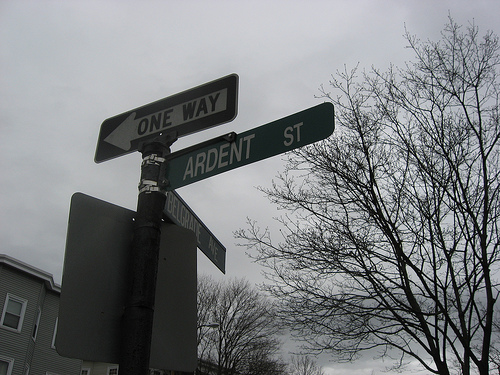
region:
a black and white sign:
[93, 73, 240, 165]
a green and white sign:
[166, 100, 337, 192]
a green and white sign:
[163, 186, 225, 271]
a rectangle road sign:
[54, 193, 198, 373]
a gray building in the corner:
[1, 253, 121, 374]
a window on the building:
[3, 293, 25, 330]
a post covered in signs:
[55, 73, 337, 374]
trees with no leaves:
[189, 13, 496, 370]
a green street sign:
[170, 101, 336, 188]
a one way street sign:
[93, 71, 238, 162]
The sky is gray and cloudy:
[16, 6, 388, 63]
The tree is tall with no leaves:
[303, 15, 499, 370]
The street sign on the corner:
[43, 60, 340, 372]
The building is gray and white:
[4, 244, 119, 373]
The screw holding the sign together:
[218, 121, 239, 144]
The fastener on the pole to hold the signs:
[135, 149, 172, 203]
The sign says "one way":
[80, 68, 255, 165]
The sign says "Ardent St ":
[168, 99, 336, 195]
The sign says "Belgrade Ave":
[159, 183, 231, 276]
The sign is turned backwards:
[58, 180, 210, 372]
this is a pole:
[108, 144, 173, 353]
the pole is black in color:
[106, 215, 165, 348]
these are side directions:
[101, 68, 338, 180]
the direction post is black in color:
[99, 78, 237, 136]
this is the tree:
[302, 160, 494, 373]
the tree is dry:
[308, 173, 475, 352]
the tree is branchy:
[352, 145, 498, 366]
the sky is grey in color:
[86, 4, 221, 64]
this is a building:
[6, 288, 35, 351]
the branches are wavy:
[293, 225, 356, 312]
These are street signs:
[17, 30, 390, 373]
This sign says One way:
[72, 76, 240, 151]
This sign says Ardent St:
[158, 141, 367, 178]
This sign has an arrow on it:
[84, 48, 251, 150]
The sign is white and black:
[99, 81, 249, 162]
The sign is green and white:
[175, 134, 370, 176]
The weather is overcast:
[13, 15, 495, 288]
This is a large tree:
[344, 144, 476, 307]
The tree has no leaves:
[319, 74, 480, 224]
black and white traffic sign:
[93, 71, 241, 164]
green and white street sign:
[154, 99, 339, 196]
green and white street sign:
[162, 180, 229, 275]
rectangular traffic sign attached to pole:
[54, 191, 209, 373]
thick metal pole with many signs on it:
[113, 129, 180, 373]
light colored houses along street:
[0, 245, 269, 373]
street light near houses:
[178, 317, 223, 344]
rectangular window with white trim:
[0, 291, 29, 334]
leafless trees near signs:
[231, 6, 498, 373]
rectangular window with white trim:
[30, 302, 45, 342]